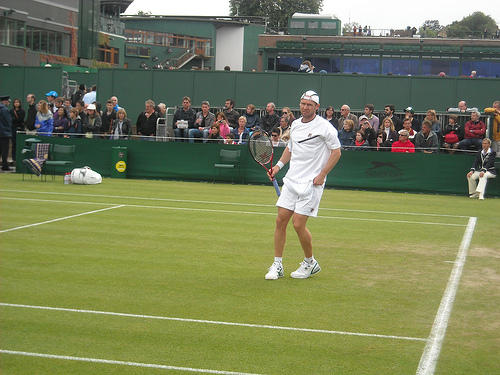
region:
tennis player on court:
[202, 71, 419, 298]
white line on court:
[98, 271, 188, 332]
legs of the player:
[258, 206, 324, 257]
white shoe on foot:
[256, 245, 288, 290]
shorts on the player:
[266, 169, 324, 225]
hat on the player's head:
[291, 85, 330, 112]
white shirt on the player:
[271, 120, 340, 186]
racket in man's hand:
[228, 123, 291, 198]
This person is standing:
[205, 78, 368, 320]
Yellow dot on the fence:
[103, 149, 131, 183]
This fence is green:
[101, 140, 165, 172]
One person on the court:
[222, 76, 367, 326]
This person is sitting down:
[455, 127, 499, 215]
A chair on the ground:
[13, 135, 82, 181]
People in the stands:
[5, 68, 244, 156]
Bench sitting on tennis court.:
[39, 143, 79, 185]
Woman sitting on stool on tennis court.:
[465, 134, 497, 205]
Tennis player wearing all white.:
[287, 88, 327, 280]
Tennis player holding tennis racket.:
[242, 93, 332, 240]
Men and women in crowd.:
[175, 95, 255, 140]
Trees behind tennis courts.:
[405, 10, 495, 35]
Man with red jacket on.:
[390, 122, 415, 147]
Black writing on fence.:
[360, 156, 418, 182]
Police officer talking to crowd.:
[1, 93, 17, 175]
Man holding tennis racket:
[263, 86, 344, 283]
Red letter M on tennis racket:
[257, 149, 271, 160]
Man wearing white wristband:
[265, 89, 342, 279]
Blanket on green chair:
[27, 140, 51, 176]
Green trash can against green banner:
[110, 142, 127, 177]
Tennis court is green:
[0, 170, 499, 373]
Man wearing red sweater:
[388, 128, 414, 150]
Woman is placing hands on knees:
[464, 135, 496, 201]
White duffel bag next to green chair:
[72, 167, 102, 185]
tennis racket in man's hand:
[242, 129, 282, 194]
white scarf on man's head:
[299, 91, 321, 105]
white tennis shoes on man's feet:
[265, 258, 320, 283]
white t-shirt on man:
[283, 120, 340, 180]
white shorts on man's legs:
[272, 178, 325, 215]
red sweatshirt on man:
[390, 138, 415, 151]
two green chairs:
[21, 139, 74, 179]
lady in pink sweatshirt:
[212, 110, 232, 136]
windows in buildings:
[0, 15, 211, 64]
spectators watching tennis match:
[0, 91, 497, 152]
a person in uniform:
[241, 52, 350, 291]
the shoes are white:
[254, 250, 326, 280]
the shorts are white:
[272, 164, 327, 221]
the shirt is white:
[277, 108, 359, 181]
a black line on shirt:
[295, 129, 330, 152]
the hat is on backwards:
[300, 88, 317, 107]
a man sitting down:
[460, 125, 499, 197]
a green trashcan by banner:
[106, 138, 132, 180]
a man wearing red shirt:
[387, 125, 418, 151]